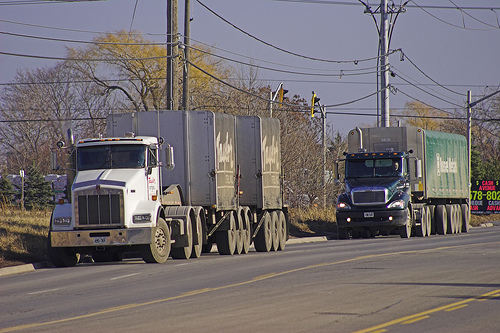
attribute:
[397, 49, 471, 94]
wires — electrical 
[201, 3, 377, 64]
wires — electrical 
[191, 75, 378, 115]
wires — electrical 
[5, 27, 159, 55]
wires — electrical 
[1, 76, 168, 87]
wires — electrical 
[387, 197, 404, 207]
lights — lit up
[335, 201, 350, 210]
lights — lit up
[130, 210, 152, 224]
lights — lit up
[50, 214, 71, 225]
lights — lit up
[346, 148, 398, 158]
lights — lit up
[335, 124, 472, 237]
semi trailer — green, eighteen wheel 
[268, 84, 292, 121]
street sign — yellow, black 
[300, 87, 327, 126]
street sign — yellow, black 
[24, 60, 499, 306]
trucks — semi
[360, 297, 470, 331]
line — yellow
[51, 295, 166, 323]
line — yellow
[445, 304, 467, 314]
line — yellow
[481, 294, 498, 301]
line — yellow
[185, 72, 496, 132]
wires — electric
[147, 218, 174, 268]
tire — black 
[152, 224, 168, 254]
rim — white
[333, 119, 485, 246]
truck — white , green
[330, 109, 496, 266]
truck — blue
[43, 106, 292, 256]
truck — white, silver 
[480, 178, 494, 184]
word — neon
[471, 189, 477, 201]
number — neon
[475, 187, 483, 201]
number — neon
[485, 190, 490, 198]
number — neon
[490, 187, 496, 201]
number — neon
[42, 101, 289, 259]
semi truck — grey , white 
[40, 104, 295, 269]
semi truck — white and gray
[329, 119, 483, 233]
semitrailer — green 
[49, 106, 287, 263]
semi trailer — white 